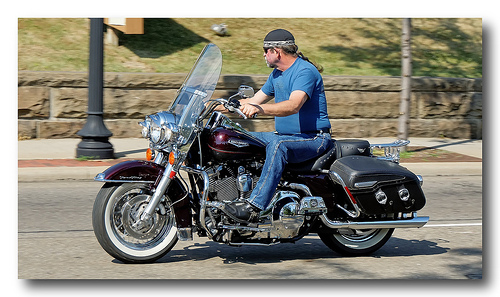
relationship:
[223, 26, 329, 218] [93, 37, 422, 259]
man riding motorcycle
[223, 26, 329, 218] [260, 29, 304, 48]
man wearing hat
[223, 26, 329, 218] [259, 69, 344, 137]
man wearing shirt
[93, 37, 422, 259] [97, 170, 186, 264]
motorcycle has wheel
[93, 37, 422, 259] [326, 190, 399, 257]
motorcycle has wheel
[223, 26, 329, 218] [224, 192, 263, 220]
man has foot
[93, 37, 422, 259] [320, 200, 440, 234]
motorcycle has muffler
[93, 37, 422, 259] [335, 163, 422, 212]
motorcycle has saddle bag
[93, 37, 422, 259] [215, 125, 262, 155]
motorcycle has gas tank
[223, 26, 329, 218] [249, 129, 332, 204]
man wearing pants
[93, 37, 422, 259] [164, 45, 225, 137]
motorcycle has windshield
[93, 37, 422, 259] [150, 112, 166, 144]
motorcycle has light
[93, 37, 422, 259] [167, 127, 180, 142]
motorcycle has light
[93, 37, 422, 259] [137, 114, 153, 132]
motorcycle has light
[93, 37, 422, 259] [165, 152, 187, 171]
motorcycle has turn signal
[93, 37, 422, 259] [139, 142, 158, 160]
motorcycle has turn signal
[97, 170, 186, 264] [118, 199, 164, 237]
wheel has spokes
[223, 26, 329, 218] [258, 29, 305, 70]
man has head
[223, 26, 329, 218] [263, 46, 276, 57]
man wearing sunglasses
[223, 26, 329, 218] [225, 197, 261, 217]
man wearing boots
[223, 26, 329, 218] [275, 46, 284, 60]
man has ear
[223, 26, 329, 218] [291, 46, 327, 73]
man has hair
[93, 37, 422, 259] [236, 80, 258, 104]
motorcycle has mirror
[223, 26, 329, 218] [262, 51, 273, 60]
man has nose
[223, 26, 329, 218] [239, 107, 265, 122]
man has hand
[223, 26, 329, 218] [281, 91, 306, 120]
man has elbow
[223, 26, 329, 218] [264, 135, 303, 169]
man has knee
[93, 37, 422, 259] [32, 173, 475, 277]
motorcycle on road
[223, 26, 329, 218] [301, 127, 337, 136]
man wearing belt